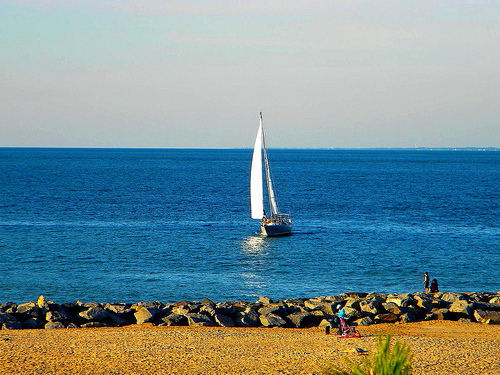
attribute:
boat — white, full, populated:
[248, 107, 300, 240]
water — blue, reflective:
[1, 148, 499, 293]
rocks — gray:
[1, 296, 499, 329]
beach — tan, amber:
[4, 329, 499, 374]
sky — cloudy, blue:
[1, 1, 498, 148]